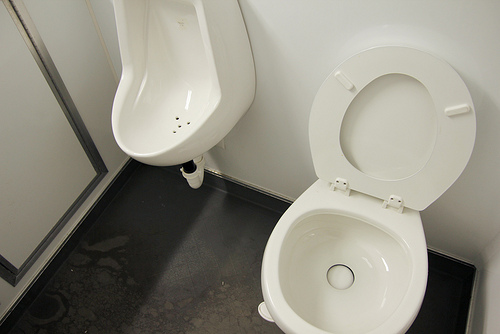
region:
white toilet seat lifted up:
[306, 39, 481, 207]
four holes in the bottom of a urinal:
[154, 83, 199, 150]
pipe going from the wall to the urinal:
[180, 159, 214, 194]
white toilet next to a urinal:
[268, 48, 461, 326]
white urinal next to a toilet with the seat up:
[77, 3, 258, 182]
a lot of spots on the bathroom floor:
[48, 248, 228, 327]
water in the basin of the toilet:
[316, 251, 366, 300]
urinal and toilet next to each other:
[64, 5, 462, 331]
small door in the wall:
[7, 6, 109, 273]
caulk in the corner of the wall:
[82, 5, 114, 61]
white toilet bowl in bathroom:
[280, 193, 412, 310]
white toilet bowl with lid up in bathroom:
[293, 200, 411, 321]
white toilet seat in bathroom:
[335, 37, 475, 212]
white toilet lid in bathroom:
[375, 93, 420, 158]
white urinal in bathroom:
[102, 12, 252, 167]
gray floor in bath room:
[85, 233, 165, 290]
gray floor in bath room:
[175, 263, 216, 303]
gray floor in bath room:
[211, 196, 246, 243]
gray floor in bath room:
[441, 272, 458, 313]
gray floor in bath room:
[121, 179, 166, 225]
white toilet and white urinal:
[55, 2, 498, 332]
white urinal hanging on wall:
[65, 3, 261, 176]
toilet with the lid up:
[262, 38, 467, 330]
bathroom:
[1, 60, 486, 331]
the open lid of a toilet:
[305, 27, 472, 208]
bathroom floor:
[65, 215, 225, 326]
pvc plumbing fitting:
[175, 163, 206, 185]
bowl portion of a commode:
[256, 198, 421, 330]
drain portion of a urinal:
[140, 101, 200, 141]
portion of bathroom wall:
[3, 10, 98, 214]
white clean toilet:
[261, 42, 482, 332]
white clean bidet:
[106, 2, 258, 190]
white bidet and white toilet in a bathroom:
[115, 0, 482, 332]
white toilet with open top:
[262, 35, 478, 328]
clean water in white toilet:
[307, 226, 397, 331]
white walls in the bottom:
[2, 1, 494, 331]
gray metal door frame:
[0, 10, 112, 283]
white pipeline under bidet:
[182, 148, 219, 185]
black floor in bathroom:
[7, 142, 482, 330]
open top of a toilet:
[311, 36, 486, 231]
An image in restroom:
[5, 8, 498, 328]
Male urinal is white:
[103, 4, 253, 167]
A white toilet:
[271, 44, 466, 332]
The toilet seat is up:
[310, 40, 441, 200]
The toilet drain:
[305, 230, 361, 311]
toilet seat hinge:
[370, 190, 425, 210]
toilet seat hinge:
[325, 180, 350, 195]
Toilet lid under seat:
[350, 105, 422, 157]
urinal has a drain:
[165, 106, 195, 133]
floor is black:
[74, 216, 241, 332]